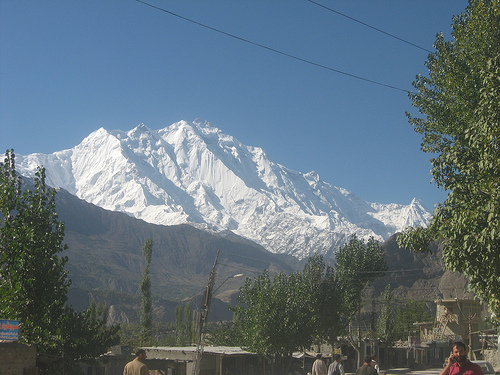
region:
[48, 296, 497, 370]
A small village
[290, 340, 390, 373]
People in a village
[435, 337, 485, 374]
A man in a red shirt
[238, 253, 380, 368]
Trees in a village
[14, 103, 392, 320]
a mountain in the background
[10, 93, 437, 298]
a mountain in the distance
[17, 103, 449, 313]
A snow covered mountain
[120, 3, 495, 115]
Power lines against a blue sky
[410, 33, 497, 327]
a tree in a village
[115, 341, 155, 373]
a man in a village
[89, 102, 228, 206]
The mountain has snow on it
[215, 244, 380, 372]
The tree has green leaves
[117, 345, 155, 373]
The person is walking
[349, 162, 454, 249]
The sky is blue and clear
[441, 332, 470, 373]
The man is on the phone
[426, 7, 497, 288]
The tree is tall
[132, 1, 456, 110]
Power lines are above the street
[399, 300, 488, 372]
Buildings are in the back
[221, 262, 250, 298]
The light is off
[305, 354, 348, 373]
The people are together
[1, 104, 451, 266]
A snow-covered mountain top.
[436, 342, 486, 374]
A man that appears to be on his phone.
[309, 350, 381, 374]
Four people standing close together.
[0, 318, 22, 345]
A sign with red, white, and blue paint.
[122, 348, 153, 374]
A man with a short haircut.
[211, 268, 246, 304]
A street light.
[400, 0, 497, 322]
Part of a very tall tree.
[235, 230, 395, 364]
A group of small trees.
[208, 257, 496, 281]
An electrical line.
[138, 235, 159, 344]
A very skinny tree.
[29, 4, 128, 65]
this is the sky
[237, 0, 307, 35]
the sky is blue in color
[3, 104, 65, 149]
the sky has some clouds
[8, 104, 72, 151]
the clouds are white in color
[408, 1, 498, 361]
this is a tree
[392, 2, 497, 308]
the tree is tall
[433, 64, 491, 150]
the leaves are green in color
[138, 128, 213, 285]
this is a mountain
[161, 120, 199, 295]
the mountain is full of snow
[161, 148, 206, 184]
the snow is white in color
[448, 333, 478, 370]
man holding cell phone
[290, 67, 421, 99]
wire in the air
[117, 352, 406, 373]
people on the street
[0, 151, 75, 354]
trees against the mountains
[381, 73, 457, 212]
branches of the tree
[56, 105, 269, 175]
mountains against the sky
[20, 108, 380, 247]
snow on the mountains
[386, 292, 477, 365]
building in the town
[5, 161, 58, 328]
leaves on the trees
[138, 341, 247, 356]
roof of the building